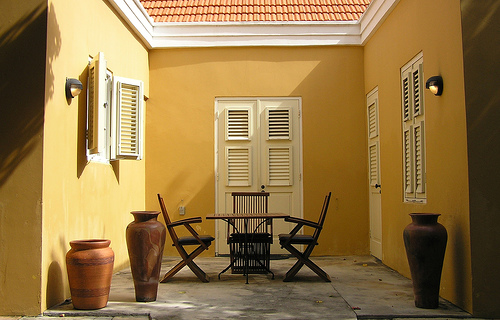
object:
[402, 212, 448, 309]
urn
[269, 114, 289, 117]
slat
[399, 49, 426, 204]
window shutters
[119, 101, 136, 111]
woon slat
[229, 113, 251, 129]
shudder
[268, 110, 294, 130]
shudder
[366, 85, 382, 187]
blinds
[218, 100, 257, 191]
blinds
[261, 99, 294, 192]
blinds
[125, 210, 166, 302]
vases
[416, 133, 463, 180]
ground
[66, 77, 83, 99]
light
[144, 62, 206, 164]
motorcycle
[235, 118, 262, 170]
wall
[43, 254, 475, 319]
concrete patio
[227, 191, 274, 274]
chair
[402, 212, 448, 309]
many bikes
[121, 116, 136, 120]
slat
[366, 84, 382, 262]
white door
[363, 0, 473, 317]
wall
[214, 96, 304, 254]
door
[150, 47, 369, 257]
wall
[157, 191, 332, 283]
three chairs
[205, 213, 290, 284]
table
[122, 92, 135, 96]
slat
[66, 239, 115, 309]
urn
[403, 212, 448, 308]
vase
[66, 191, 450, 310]
furniture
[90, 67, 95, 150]
shutters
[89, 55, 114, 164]
window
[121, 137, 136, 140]
slat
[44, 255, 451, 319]
porch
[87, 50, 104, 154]
shutter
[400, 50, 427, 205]
window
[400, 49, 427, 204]
shutters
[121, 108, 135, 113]
wooden slat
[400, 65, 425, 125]
shudder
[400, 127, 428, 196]
shudder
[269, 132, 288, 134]
wooden slat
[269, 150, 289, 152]
wooden slat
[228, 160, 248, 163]
wooden slat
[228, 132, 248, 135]
wooden slat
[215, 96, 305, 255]
shutter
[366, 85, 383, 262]
shutter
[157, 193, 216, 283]
chair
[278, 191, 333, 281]
chair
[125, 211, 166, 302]
urn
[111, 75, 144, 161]
shutter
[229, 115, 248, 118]
wooden slat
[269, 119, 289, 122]
wooden slat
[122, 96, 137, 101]
wooden slat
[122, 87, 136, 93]
wooden slat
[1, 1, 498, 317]
house exterior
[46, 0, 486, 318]
outdoor patio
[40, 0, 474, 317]
patio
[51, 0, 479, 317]
courtyard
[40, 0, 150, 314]
walls